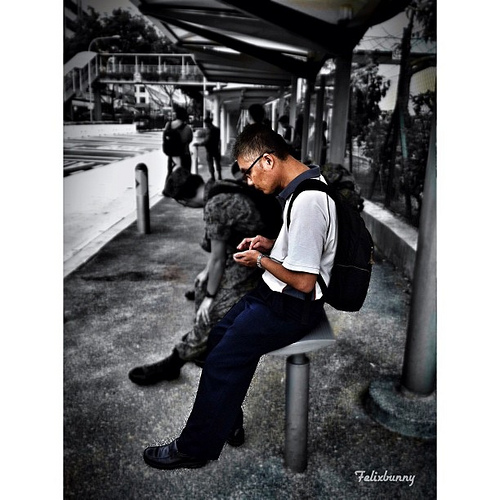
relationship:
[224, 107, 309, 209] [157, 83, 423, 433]
head of man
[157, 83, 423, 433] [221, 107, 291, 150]
man with hair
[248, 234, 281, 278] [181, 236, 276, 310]
watch on wrist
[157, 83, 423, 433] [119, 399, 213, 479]
man has foot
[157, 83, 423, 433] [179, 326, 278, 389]
man has knee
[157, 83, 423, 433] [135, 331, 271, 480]
man has leg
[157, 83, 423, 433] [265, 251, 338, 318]
man has elbow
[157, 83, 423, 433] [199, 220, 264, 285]
man has hand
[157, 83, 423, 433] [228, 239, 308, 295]
man has arm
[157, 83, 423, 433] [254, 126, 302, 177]
man has ear